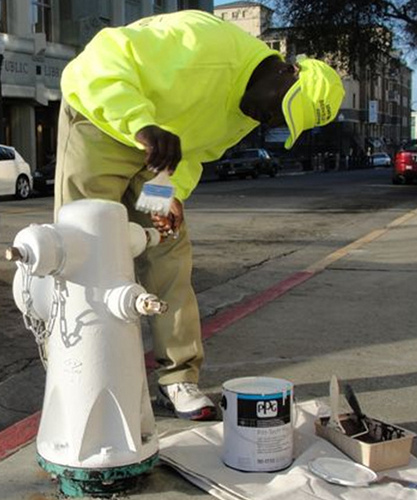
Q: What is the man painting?
A: Hydrant.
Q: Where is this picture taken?
A: Sidewalk.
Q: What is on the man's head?
A: Hat.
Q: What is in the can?
A: Paint.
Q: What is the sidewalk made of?
A: Concrete.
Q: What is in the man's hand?
A: Brush.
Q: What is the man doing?
A: Painting.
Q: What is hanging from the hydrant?
A: Chain.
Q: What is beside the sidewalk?
A: Road.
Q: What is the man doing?
A: Painting,.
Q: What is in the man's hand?
A: Paint brush.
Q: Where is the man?
A: On the sidewalk.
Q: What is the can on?
A: Newspaper.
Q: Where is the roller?
A: In the bucket.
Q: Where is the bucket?
A: On the newspaper.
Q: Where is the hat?
A: Man's head.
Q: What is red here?
A: The curb.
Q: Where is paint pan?
A: On the tarp.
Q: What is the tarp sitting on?
A: The sidewalk.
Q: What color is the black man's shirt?
A: Light Green.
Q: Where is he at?
A: On a sidewalk by a city street.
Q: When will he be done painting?
A: He will be done soon.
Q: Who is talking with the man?
A: Nobody.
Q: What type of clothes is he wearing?
A: Casual and construction type clothes.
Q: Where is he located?
A: On a sidewalk.